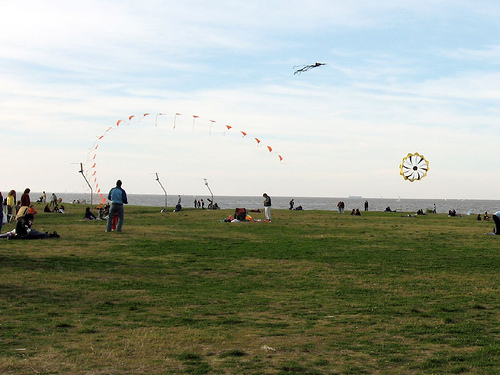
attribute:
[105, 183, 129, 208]
jacket — blue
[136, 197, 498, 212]
gray sea — quiet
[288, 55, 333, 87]
kite — blue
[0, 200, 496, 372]
grass — green, brown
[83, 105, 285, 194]
kites — orange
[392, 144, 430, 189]
object — circular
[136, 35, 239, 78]
clouds — white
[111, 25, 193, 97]
sky — blue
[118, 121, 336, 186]
kites — orange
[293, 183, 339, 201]
lake — grey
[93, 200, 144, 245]
jeans — blue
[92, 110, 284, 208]
kites — orange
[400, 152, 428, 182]
kite — round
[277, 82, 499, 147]
clouds — white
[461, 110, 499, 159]
clouds — white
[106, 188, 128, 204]
jacket — blue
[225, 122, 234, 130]
kites — orange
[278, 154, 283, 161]
kites — orange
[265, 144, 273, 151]
kites — orange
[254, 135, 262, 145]
kites — orange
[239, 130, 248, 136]
kites — orange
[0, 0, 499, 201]
clouds — white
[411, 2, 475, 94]
sky — blue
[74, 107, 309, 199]
kites — orange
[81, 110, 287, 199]
tail — long, orange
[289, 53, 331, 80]
kite — flying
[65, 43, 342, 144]
sky — cloudy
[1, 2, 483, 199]
sky — blue